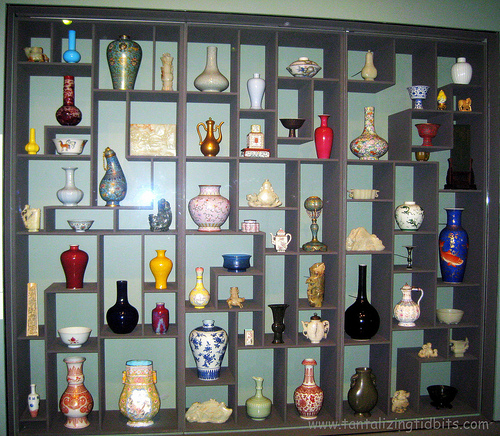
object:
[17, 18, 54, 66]
cabinet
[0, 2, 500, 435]
wall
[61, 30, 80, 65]
vase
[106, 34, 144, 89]
vase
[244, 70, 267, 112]
vase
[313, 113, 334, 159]
vase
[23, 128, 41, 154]
vase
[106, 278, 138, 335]
vase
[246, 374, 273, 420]
vase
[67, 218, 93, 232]
bowl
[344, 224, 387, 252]
vase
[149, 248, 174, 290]
vase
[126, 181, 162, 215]
light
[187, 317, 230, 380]
vase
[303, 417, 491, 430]
text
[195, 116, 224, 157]
teapot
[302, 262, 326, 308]
vase